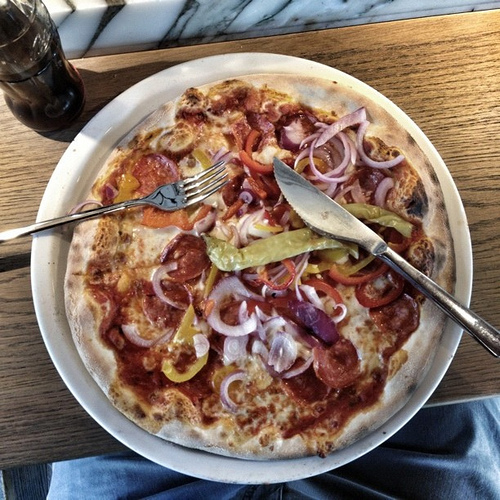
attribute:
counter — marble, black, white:
[42, 0, 500, 58]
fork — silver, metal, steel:
[0, 161, 229, 245]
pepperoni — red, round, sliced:
[162, 235, 209, 280]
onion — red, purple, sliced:
[291, 102, 404, 207]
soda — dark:
[0, 1, 86, 132]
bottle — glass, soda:
[0, 1, 87, 135]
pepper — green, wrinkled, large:
[201, 203, 415, 271]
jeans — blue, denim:
[45, 396, 499, 498]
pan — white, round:
[28, 51, 474, 487]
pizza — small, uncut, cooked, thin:
[62, 72, 457, 463]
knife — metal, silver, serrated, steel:
[271, 152, 499, 355]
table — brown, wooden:
[0, 10, 499, 470]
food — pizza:
[63, 75, 455, 464]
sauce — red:
[107, 324, 385, 440]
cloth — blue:
[48, 397, 498, 499]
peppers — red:
[238, 129, 292, 196]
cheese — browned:
[100, 91, 392, 433]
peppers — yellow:
[161, 296, 210, 384]